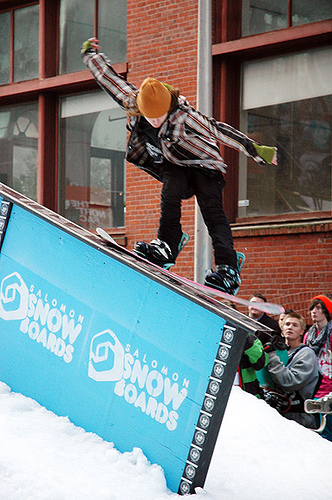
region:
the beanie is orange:
[135, 77, 169, 115]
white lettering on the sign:
[115, 342, 188, 431]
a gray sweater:
[268, 344, 316, 397]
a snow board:
[96, 226, 283, 315]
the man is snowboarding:
[81, 37, 283, 318]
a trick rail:
[0, 186, 270, 493]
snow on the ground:
[1, 380, 174, 499]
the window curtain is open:
[243, 47, 331, 110]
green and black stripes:
[238, 335, 269, 395]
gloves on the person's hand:
[80, 35, 98, 55]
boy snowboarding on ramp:
[65, 24, 302, 312]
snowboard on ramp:
[91, 213, 297, 319]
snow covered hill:
[1, 361, 327, 496]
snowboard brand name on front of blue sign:
[86, 313, 196, 442]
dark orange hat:
[131, 75, 174, 120]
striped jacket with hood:
[84, 48, 265, 209]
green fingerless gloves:
[78, 36, 99, 55]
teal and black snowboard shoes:
[129, 217, 253, 293]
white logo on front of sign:
[85, 320, 128, 388]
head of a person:
[125, 74, 176, 129]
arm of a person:
[83, 32, 131, 105]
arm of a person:
[212, 110, 255, 150]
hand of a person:
[73, 27, 111, 62]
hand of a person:
[261, 135, 286, 164]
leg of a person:
[158, 189, 203, 232]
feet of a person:
[136, 238, 177, 262]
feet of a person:
[185, 264, 250, 302]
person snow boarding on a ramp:
[90, 215, 285, 323]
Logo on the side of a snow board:
[0, 266, 198, 447]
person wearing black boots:
[133, 224, 247, 296]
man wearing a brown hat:
[129, 65, 179, 125]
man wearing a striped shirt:
[77, 48, 286, 177]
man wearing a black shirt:
[141, 116, 176, 160]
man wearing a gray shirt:
[261, 339, 323, 405]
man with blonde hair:
[272, 307, 309, 332]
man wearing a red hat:
[308, 293, 330, 320]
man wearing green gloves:
[248, 137, 279, 167]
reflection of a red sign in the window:
[65, 184, 108, 228]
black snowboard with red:
[95, 225, 283, 311]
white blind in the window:
[239, 48, 329, 108]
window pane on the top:
[11, 6, 39, 77]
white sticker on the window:
[237, 199, 248, 206]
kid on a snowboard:
[81, 36, 278, 286]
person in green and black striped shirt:
[216, 294, 286, 411]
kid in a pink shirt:
[301, 294, 330, 435]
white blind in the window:
[60, 86, 116, 117]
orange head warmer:
[309, 293, 331, 313]